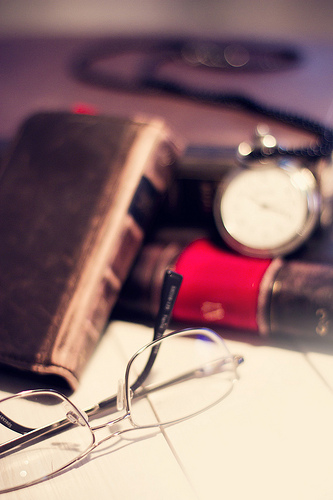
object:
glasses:
[0, 267, 245, 491]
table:
[0, 310, 333, 500]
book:
[0, 105, 188, 395]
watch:
[213, 158, 319, 260]